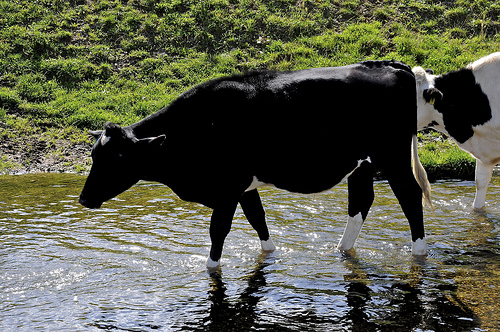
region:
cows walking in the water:
[56, 27, 487, 275]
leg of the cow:
[206, 213, 234, 261]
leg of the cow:
[248, 220, 275, 246]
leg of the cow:
[343, 201, 369, 253]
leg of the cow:
[406, 198, 426, 250]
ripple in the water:
[359, 282, 396, 303]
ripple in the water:
[170, 297, 210, 325]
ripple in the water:
[81, 287, 108, 310]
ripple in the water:
[280, 261, 313, 281]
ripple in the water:
[362, 312, 391, 329]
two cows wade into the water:
[48, 11, 486, 303]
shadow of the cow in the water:
[185, 265, 442, 330]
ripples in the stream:
[16, 212, 166, 242]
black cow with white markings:
[85, 67, 415, 218]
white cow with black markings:
[412, 55, 493, 200]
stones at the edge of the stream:
[7, 130, 78, 170]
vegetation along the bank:
[10, 50, 155, 101]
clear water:
[465, 271, 495, 302]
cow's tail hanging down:
[415, 152, 432, 207]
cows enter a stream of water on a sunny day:
[46, 7, 492, 273]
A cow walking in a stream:
[79, 59, 432, 266]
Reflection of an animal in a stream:
[101, 263, 499, 330]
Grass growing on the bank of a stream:
[1, 3, 78, 215]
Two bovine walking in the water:
[79, 50, 499, 272]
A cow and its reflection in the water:
[80, 61, 480, 330]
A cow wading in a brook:
[77, 60, 436, 269]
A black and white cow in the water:
[78, 60, 432, 267]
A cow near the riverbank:
[6, 25, 433, 267]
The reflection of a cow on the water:
[74, 259, 495, 330]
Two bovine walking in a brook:
[77, 63, 499, 270]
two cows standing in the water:
[62, 33, 497, 286]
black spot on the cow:
[429, 60, 489, 146]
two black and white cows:
[72, 46, 499, 284]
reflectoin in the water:
[194, 271, 270, 331]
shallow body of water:
[7, 174, 499, 330]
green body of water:
[0, 173, 492, 328]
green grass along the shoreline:
[3, 3, 496, 188]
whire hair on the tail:
[404, 136, 449, 214]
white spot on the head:
[94, 131, 112, 148]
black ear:
[422, 83, 442, 103]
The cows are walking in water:
[48, 22, 493, 313]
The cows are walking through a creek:
[46, 12, 496, 303]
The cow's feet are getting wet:
[60, 31, 491, 313]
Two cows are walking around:
[52, 37, 497, 304]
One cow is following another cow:
[66, 32, 496, 293]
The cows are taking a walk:
[60, 22, 497, 318]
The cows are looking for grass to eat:
[66, 36, 497, 296]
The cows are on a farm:
[40, 20, 496, 305]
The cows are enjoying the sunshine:
[50, 23, 496, 298]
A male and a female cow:
[61, 42, 498, 301]